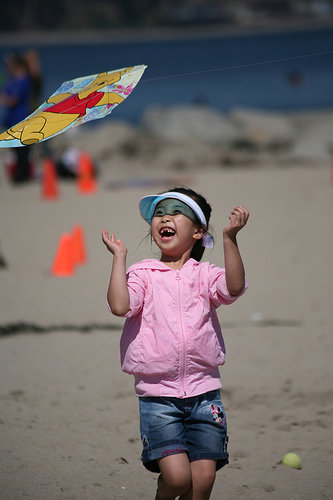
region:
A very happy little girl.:
[101, 186, 249, 499]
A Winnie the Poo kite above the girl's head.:
[1, 64, 147, 148]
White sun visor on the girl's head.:
[136, 192, 208, 226]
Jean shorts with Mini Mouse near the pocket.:
[138, 388, 229, 471]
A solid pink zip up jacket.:
[106, 258, 246, 399]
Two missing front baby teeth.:
[159, 228, 173, 236]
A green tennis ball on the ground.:
[282, 449, 301, 471]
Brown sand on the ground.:
[0, 110, 332, 499]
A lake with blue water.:
[0, 29, 332, 130]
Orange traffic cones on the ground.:
[41, 151, 96, 275]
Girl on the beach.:
[92, 172, 245, 498]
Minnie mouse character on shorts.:
[204, 400, 226, 427]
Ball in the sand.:
[280, 448, 305, 476]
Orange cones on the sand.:
[51, 221, 89, 286]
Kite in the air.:
[1, 58, 153, 159]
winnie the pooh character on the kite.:
[2, 63, 139, 147]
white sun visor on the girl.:
[134, 177, 217, 260]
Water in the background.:
[0, 31, 331, 134]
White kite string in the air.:
[140, 41, 330, 89]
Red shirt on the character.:
[41, 75, 112, 122]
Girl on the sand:
[101, 184, 248, 499]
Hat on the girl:
[137, 191, 214, 249]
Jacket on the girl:
[104, 255, 247, 397]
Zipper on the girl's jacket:
[174, 270, 186, 397]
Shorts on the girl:
[138, 389, 230, 473]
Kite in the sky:
[1, 63, 147, 148]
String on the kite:
[121, 50, 332, 87]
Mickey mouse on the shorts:
[210, 403, 227, 427]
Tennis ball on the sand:
[279, 450, 301, 470]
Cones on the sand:
[39, 149, 96, 276]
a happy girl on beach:
[91, 156, 271, 498]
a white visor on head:
[135, 190, 213, 248]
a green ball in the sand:
[276, 446, 312, 485]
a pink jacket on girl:
[87, 247, 251, 408]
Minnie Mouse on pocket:
[209, 402, 228, 445]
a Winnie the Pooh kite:
[22, 41, 140, 177]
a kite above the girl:
[23, 42, 156, 185]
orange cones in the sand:
[42, 214, 109, 309]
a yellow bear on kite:
[20, 55, 134, 183]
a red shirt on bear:
[41, 87, 119, 129]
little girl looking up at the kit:
[99, 185, 248, 498]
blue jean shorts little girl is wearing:
[139, 389, 228, 471]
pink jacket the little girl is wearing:
[118, 258, 237, 399]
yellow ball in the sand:
[283, 452, 298, 470]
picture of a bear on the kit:
[0, 68, 129, 145]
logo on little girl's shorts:
[208, 403, 223, 427]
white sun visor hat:
[138, 188, 207, 225]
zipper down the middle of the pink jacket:
[172, 268, 187, 395]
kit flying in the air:
[1, 64, 148, 148]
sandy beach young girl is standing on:
[0, 166, 332, 498]